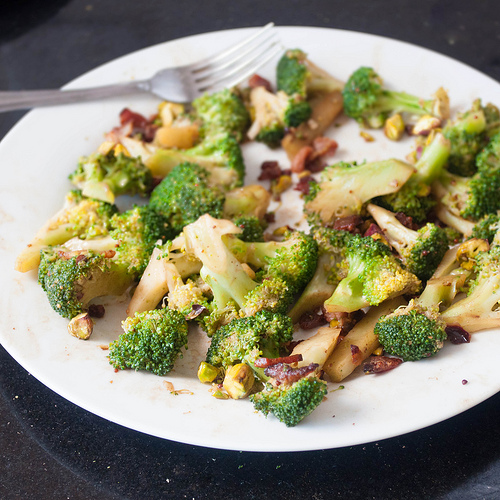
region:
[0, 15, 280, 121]
Silver fork on round white plate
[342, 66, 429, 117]
Broccoli on white round plate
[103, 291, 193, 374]
Broccoli on white round plate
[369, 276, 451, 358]
Broccoli on white round plate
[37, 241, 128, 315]
Broccoli on white round plate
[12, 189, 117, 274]
Broccoli on white round plate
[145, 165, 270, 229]
Broccoli on white round plate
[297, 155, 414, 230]
Broccoli on white round plate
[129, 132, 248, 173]
Broccoli on white round plate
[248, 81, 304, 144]
Broccoli on white round plate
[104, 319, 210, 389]
the plate is white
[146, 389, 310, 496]
the plate is white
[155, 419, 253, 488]
the plate is white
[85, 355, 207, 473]
the plate is white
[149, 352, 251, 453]
the plate is white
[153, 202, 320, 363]
florets of green broccoli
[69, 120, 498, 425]
broccoli on white plate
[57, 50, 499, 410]
round white plate on black table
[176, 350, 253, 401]
pieces of nuts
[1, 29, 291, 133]
silver fork on plate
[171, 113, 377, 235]
pieces of nuts and broccoli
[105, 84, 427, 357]
vegetables on a plate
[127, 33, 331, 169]
fork next to broccoli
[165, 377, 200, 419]
crumbs on a plate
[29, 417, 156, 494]
black table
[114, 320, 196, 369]
Green brocolli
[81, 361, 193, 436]
A white plate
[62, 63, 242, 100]
A silver fork.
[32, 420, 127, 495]
The reflection of the white plate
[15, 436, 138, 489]
The white plate is on the black table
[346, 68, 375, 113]
Green brocolli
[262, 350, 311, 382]
A red pepper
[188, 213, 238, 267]
A stem of the brocolli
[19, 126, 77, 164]
A white plate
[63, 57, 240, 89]
A silver fork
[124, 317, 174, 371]
fresh green delicious broccoli